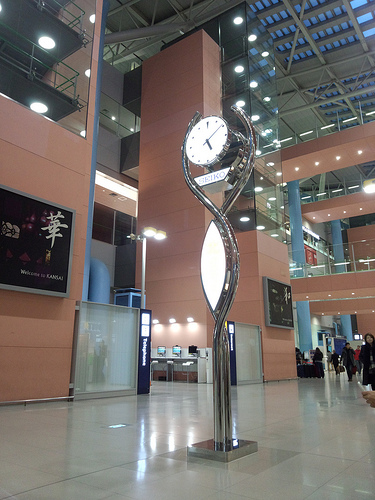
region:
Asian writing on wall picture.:
[27, 208, 67, 251]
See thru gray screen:
[70, 301, 138, 407]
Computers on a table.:
[153, 339, 203, 360]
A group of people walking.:
[312, 324, 374, 400]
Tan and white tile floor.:
[272, 401, 321, 482]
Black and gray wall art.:
[257, 279, 295, 335]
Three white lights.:
[300, 282, 363, 305]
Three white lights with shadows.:
[150, 309, 199, 329]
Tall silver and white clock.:
[155, 96, 267, 465]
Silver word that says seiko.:
[190, 159, 237, 196]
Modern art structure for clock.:
[178, 104, 266, 466]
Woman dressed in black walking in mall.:
[355, 328, 373, 389]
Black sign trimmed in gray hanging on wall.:
[3, 187, 79, 301]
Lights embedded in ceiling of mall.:
[289, 145, 370, 179]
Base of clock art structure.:
[183, 430, 263, 468]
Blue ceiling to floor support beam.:
[286, 178, 313, 375]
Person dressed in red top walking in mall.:
[348, 344, 365, 371]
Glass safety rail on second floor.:
[291, 239, 372, 274]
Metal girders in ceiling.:
[276, 9, 372, 126]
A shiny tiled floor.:
[272, 396, 358, 494]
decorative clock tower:
[169, 104, 265, 484]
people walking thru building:
[330, 334, 373, 410]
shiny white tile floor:
[68, 397, 168, 499]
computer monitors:
[152, 340, 198, 367]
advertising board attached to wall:
[256, 271, 297, 334]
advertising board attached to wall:
[4, 176, 83, 308]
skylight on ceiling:
[257, 9, 367, 118]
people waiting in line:
[289, 346, 331, 380]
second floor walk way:
[282, 245, 371, 337]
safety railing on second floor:
[10, 20, 89, 114]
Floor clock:
[161, 88, 284, 471]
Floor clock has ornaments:
[162, 87, 277, 485]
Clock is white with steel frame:
[167, 107, 233, 169]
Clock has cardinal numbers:
[170, 108, 234, 168]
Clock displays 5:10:
[175, 112, 229, 166]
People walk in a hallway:
[287, 309, 367, 403]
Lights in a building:
[16, 3, 94, 138]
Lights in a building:
[227, 10, 302, 237]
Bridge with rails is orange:
[285, 255, 370, 306]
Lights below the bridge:
[273, 100, 371, 193]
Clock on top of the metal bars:
[186, 112, 229, 169]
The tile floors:
[0, 371, 372, 499]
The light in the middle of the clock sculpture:
[198, 214, 237, 314]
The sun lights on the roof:
[240, 1, 373, 130]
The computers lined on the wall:
[155, 343, 198, 359]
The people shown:
[291, 326, 372, 410]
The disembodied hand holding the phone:
[345, 376, 373, 410]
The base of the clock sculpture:
[187, 430, 260, 464]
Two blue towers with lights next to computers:
[134, 303, 236, 403]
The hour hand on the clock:
[201, 138, 214, 152]